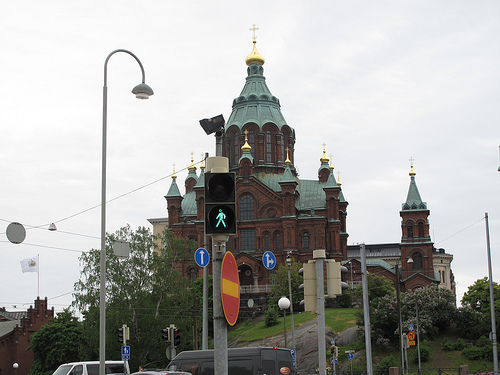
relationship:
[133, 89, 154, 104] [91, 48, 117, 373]
light on pole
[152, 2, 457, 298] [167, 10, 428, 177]
building with crosses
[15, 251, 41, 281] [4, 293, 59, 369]
flag on building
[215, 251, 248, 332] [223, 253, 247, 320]
sign means caution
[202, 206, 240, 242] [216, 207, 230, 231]
crosswalk indicates walk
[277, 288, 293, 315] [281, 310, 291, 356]
lamp has post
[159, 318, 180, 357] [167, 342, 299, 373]
traffic light by van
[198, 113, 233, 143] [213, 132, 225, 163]
camera on pole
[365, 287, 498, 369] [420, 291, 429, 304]
shrubbery has flowers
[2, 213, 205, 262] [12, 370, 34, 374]
wires above ground